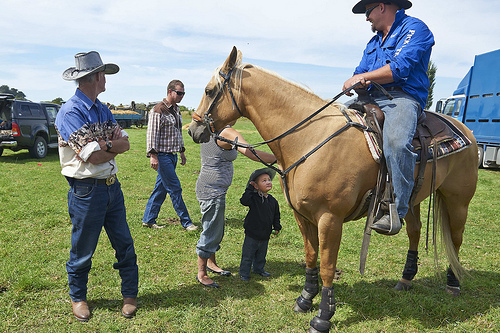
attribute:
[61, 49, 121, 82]
grey hat — cowboy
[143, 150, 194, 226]
jeans — blue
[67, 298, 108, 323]
boot — brown